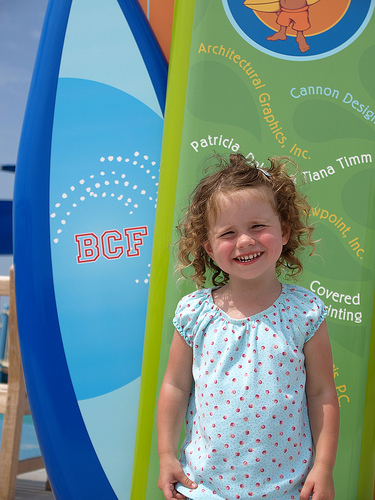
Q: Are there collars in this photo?
A: Yes, there is a collar.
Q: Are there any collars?
A: Yes, there is a collar.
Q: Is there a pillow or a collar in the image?
A: Yes, there is a collar.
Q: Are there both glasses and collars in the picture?
A: No, there is a collar but no glasses.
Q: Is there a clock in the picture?
A: No, there are no clocks.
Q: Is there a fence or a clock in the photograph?
A: No, there are no clocks or fences.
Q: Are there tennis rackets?
A: No, there are no tennis rackets.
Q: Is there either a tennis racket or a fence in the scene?
A: No, there are no rackets or fences.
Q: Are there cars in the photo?
A: No, there are no cars.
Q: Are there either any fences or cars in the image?
A: No, there are no cars or fences.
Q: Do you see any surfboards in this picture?
A: Yes, there is a surfboard.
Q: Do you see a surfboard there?
A: Yes, there is a surfboard.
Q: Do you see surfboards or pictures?
A: Yes, there is a surfboard.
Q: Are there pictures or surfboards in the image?
A: Yes, there is a surfboard.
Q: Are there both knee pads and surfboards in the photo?
A: No, there is a surfboard but no knee pads.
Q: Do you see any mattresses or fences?
A: No, there are no fences or mattresses.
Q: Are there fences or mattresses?
A: No, there are no fences or mattresses.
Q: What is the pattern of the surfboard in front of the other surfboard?
A: The surf board is dotted.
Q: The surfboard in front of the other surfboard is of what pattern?
A: The surf board is dotted.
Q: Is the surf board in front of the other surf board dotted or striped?
A: The surfboard is dotted.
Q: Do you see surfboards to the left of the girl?
A: Yes, there is a surfboard to the left of the girl.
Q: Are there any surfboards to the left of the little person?
A: Yes, there is a surfboard to the left of the girl.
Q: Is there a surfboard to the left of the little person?
A: Yes, there is a surfboard to the left of the girl.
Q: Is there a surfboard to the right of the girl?
A: No, the surfboard is to the left of the girl.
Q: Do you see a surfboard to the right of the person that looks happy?
A: No, the surfboard is to the left of the girl.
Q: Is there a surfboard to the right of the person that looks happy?
A: No, the surfboard is to the left of the girl.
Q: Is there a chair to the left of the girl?
A: No, there is a surfboard to the left of the girl.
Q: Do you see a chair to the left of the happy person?
A: No, there is a surfboard to the left of the girl.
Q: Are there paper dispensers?
A: No, there are no paper dispensers.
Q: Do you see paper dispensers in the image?
A: No, there are no paper dispensers.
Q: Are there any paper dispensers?
A: No, there are no paper dispensers.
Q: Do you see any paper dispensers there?
A: No, there are no paper dispensers.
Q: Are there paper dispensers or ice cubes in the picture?
A: No, there are no paper dispensers or ice cubes.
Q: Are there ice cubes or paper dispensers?
A: No, there are no paper dispensers or ice cubes.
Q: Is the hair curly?
A: Yes, the hair is curly.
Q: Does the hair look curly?
A: Yes, the hair is curly.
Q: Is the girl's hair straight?
A: No, the hair is curly.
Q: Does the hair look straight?
A: No, the hair is curly.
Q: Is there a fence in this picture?
A: No, there are no fences.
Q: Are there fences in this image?
A: No, there are no fences.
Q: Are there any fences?
A: No, there are no fences.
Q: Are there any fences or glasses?
A: No, there are no fences or glasses.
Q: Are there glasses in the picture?
A: No, there are no glasses.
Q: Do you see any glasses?
A: No, there are no glasses.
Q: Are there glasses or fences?
A: No, there are no glasses or fences.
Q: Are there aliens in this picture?
A: No, there are no aliens.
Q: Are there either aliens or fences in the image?
A: No, there are no aliens or fences.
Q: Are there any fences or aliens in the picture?
A: No, there are no aliens or fences.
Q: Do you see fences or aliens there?
A: No, there are no aliens or fences.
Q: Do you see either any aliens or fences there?
A: No, there are no aliens or fences.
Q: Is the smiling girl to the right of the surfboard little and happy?
A: Yes, the girl is little and happy.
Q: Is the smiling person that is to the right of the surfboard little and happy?
A: Yes, the girl is little and happy.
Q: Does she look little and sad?
A: No, the girl is little but happy.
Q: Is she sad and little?
A: No, the girl is little but happy.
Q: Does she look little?
A: Yes, the girl is little.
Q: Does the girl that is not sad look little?
A: Yes, the girl is little.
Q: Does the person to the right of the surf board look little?
A: Yes, the girl is little.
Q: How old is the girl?
A: The girl is little.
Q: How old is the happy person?
A: The girl is little.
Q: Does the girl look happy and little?
A: Yes, the girl is happy and little.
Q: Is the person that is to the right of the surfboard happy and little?
A: Yes, the girl is happy and little.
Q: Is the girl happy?
A: Yes, the girl is happy.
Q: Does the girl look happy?
A: Yes, the girl is happy.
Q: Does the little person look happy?
A: Yes, the girl is happy.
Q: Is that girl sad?
A: No, the girl is happy.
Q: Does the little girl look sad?
A: No, the girl is happy.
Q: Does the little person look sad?
A: No, the girl is happy.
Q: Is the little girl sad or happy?
A: The girl is happy.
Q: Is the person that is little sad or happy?
A: The girl is happy.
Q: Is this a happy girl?
A: Yes, this is a happy girl.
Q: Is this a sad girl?
A: No, this is a happy girl.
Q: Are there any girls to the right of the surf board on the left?
A: Yes, there is a girl to the right of the surfboard.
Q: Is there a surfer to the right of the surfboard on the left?
A: No, there is a girl to the right of the surfboard.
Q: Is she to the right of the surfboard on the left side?
A: Yes, the girl is to the right of the surfboard.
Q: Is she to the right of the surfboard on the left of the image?
A: Yes, the girl is to the right of the surfboard.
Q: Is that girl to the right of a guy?
A: No, the girl is to the right of the surfboard.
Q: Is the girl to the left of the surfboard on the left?
A: No, the girl is to the right of the surfboard.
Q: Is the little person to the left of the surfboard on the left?
A: No, the girl is to the right of the surfboard.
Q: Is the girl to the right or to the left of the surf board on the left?
A: The girl is to the right of the surfboard.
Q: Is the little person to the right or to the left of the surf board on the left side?
A: The girl is to the right of the surfboard.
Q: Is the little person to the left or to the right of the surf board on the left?
A: The girl is to the right of the surfboard.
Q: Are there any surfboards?
A: Yes, there is a surfboard.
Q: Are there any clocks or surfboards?
A: Yes, there is a surfboard.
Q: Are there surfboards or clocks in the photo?
A: Yes, there is a surfboard.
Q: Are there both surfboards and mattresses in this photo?
A: No, there is a surfboard but no mattresses.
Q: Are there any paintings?
A: No, there are no paintings.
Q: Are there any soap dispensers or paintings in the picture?
A: No, there are no paintings or soap dispensers.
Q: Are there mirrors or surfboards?
A: Yes, there is a surfboard.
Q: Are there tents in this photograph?
A: No, there are no tents.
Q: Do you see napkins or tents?
A: No, there are no tents or napkins.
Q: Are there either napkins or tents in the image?
A: No, there are no tents or napkins.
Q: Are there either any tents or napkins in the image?
A: No, there are no tents or napkins.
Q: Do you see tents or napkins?
A: No, there are no tents or napkins.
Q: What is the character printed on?
A: The character is printed on the surfboard.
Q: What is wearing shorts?
A: The character is wearing shorts.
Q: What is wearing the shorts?
A: The character is wearing shorts.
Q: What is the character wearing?
A: The character is wearing shorts.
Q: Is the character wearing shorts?
A: Yes, the character is wearing shorts.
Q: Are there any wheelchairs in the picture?
A: No, there are no wheelchairs.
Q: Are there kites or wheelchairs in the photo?
A: No, there are no wheelchairs or kites.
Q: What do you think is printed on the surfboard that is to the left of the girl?
A: The letter is printed on the surfboard.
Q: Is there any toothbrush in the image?
A: No, there are no toothbrushes.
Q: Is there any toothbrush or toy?
A: No, there are no toothbrushes or toys.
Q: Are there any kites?
A: No, there are no kites.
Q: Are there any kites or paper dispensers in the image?
A: No, there are no kites or paper dispensers.